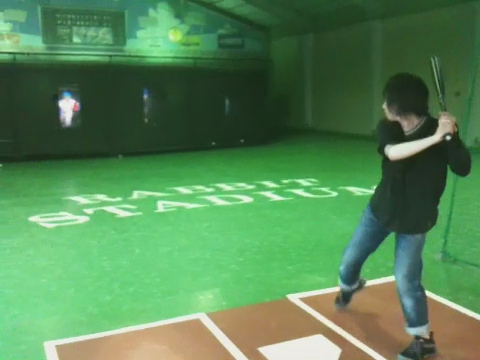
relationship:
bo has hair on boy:
[381, 73, 430, 121] [333, 72, 470, 358]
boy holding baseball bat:
[333, 72, 470, 358] [428, 54, 455, 143]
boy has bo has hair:
[333, 72, 470, 358] [381, 73, 430, 121]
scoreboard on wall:
[38, 1, 129, 47] [0, 0, 270, 159]